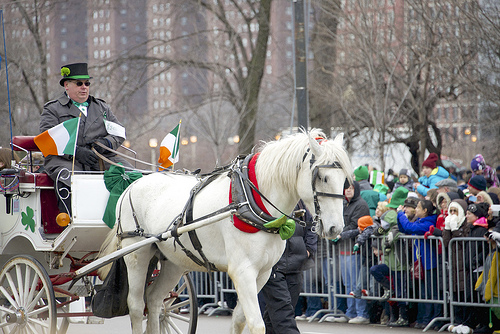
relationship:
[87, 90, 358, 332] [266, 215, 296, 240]
horse with bow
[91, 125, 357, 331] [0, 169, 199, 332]
horse pulling white carriage